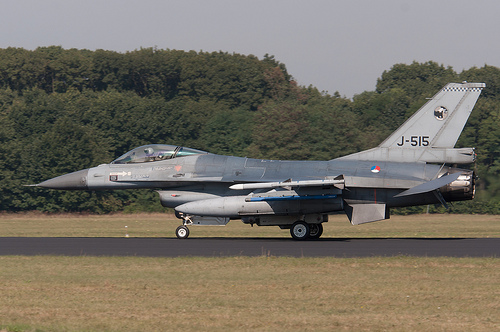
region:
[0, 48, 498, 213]
Thick, green trees clumped together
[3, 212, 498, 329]
brown dried grass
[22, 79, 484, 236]
silver aircraft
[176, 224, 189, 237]
black front wheel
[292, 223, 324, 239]
two black back wheels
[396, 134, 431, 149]
J-515 on tail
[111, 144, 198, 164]
glass cockpit with pilot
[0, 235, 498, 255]
gray concrete runway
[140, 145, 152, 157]
pilot wearing a white helmet in cockpit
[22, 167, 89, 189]
pointed front of aircraft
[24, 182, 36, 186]
Needle shaped front of plane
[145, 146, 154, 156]
Pilot in cockpit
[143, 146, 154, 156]
Pilot with hard hat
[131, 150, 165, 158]
Cockpit of plant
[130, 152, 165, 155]
The glass cockpit of plane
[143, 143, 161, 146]
Dome shaped top of plane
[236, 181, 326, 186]
Missile loaded on pane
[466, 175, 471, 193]
The metallic jet engine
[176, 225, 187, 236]
Front wheel of plane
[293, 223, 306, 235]
The rear plane wheel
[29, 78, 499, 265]
a gray military plane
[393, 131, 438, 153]
Black letters and numbers on plane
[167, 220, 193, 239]
front wheel of plane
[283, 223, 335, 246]
rear wheels of plane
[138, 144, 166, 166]
a pilot in the plane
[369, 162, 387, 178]
a red white and blue circle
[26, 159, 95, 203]
pointy end of the plane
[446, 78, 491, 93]
black and white checker strip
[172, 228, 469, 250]
shadow on ground from plane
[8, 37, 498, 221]
a line of trees behind plane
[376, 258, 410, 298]
part of a ground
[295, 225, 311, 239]
part of a wheel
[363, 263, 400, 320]
part of a ground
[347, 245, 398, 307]
part of a ground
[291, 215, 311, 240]
part of a wheel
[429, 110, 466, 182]
part of a plane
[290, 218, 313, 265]
part of a wheel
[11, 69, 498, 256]
a plane on the ground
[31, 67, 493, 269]
a gray militar plane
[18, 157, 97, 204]
nose of plane is pointy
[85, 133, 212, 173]
cockpit of a plane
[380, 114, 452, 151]
number on plane is J-515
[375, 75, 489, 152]
a number on vertical stabilizer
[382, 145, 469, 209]
fins of a plane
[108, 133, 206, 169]
a pilot inside a cockpit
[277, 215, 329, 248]
black wheels of plane